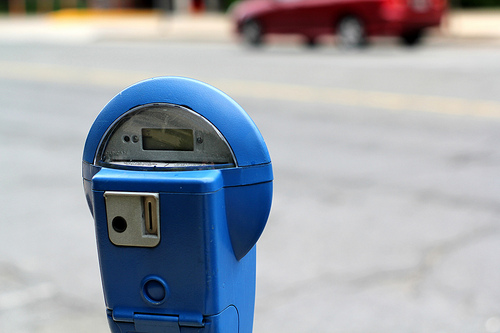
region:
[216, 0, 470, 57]
Blurry red car in background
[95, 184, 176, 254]
Light silver coin slot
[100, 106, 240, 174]
Meter screen behind glass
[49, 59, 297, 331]
Blue parking meter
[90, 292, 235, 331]
Hinges on meter box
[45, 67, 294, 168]
Rounded top of parking meter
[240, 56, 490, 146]
Blurred yellow road line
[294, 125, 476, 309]
Light grey street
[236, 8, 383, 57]
Black car tires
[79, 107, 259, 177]
Reflection on parking meter glass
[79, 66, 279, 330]
BLUE METAL PARKING METER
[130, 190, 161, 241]
PARKING METER COIN SLOT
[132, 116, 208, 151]
PARKING METER DISPLAY WINDOW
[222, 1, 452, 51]
RED CAR IN THE BACKGROUND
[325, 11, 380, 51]
BLACK WHEEL ON THE RED CAR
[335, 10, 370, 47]
HUB CAP ON THE CAR WHEEL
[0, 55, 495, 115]
PAVEMENT LINE ON THE STREET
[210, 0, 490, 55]
RED CAR ON THE STREET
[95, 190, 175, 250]
METAL COIN SLOT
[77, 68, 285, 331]
CLOSEUP PICTURE OF A PARKING METER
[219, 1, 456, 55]
a red car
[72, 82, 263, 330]
a blue parking meter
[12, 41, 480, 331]
a street for cars to drive on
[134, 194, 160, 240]
a coin slot for the parking meter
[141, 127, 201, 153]
the part that tells you the time left for the parking meter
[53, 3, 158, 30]
a yellow strip on the sidewalk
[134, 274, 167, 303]
a round circle on the parking meter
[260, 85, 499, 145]
a yellow stripe in the road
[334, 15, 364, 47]
a wheel for the car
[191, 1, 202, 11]
something red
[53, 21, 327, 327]
Parking meter in the city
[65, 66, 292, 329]
Parking meter is bright royal blue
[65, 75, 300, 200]
Parking meter screen is blank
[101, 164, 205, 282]
Parking meter coins slot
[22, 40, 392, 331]
Parking meter is alongside city street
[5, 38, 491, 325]
City street is behind the parking meter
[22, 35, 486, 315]
City street is made up of cement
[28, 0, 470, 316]
A red car is parked across the street from the parking meter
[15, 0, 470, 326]
The city street behind the parking meter has cracks in the cement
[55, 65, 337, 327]
The top of the parking meter is curved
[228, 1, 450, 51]
the car is red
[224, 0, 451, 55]
the car is blurry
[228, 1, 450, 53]
the car is parked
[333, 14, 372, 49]
wheel on a car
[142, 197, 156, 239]
a coin slot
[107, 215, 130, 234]
a key hole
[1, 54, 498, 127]
the yellow line on a road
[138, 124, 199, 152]
an empty parking meter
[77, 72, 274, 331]
a vintage parking meter